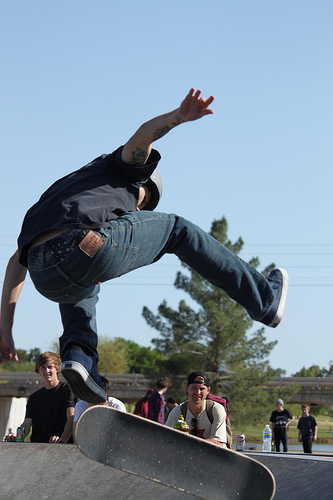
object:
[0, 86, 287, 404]
man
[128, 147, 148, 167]
tattoo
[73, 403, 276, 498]
skateboard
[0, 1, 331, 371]
sky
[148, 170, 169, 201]
cap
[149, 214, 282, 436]
tree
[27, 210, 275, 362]
jeans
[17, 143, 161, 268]
shirt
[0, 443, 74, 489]
ramp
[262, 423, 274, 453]
bottle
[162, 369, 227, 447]
boy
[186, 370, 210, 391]
hat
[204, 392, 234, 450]
backpack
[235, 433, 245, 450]
soda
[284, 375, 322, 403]
tracks